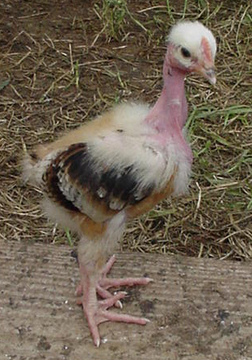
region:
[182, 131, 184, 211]
part of a chest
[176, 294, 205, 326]
part of a floor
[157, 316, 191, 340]
part of a ground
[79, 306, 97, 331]
paqrt of a leg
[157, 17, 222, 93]
Baby birds head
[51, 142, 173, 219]
brown and white wing feathers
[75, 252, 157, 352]
pink chicken feet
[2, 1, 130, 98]
grass and mud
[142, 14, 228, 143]
baby turkey's head and neck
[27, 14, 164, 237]
baby bird's body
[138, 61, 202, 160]
baby turkey's pink neck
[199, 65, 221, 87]
baby bird's brown and white beak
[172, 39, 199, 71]
Black eye of a bird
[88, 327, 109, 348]
bird's pink claw with white nail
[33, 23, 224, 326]
small turkey on plank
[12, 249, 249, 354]
wooden plank by grass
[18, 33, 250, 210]
grass on ground near plank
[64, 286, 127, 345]
pink foot of baby bird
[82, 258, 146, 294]
pink foot of baby bird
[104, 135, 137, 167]
white feathers of bird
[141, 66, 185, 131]
pink neck of bird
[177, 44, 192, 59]
small eye of bird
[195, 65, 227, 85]
yellow beak of bird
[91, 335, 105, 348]
small claw of baby bird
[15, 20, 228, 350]
A small baby bird.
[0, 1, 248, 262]
Green and brown straw on the ground.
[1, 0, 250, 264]
Green and brown hay covering the ground.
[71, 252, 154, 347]
Pink claws of a bird.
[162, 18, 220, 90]
The head of a young bird.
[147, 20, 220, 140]
A red neck of a young bird.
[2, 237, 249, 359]
A brown mat on top of grass.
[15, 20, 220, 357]
Bird standing on a brown mat.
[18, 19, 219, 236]
White and brown feathers on a bird.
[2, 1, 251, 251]
Brown and green grass near a bird.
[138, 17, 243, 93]
face of the bird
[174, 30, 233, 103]
face of the animal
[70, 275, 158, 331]
legs of the hen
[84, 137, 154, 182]
skin of the bird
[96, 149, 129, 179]
fur of the hen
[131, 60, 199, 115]
a hen with the neck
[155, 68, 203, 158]
a neck with no hairs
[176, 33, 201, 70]
eye of the hen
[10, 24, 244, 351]
a hen in the ground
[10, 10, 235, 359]
a hen in the sand